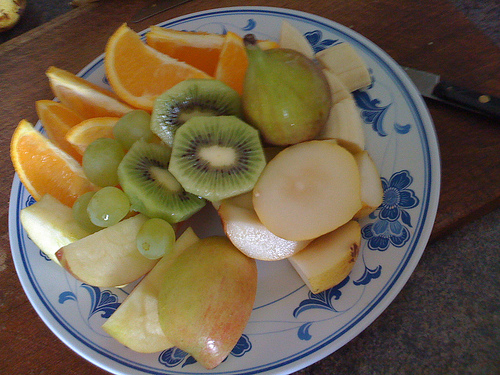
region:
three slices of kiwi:
[117, 80, 263, 220]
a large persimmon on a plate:
[240, 31, 330, 145]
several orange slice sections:
[0, 23, 251, 201]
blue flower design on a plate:
[360, 170, 417, 252]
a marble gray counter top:
[295, 206, 499, 373]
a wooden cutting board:
[3, 0, 498, 373]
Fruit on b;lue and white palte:
[10, 20, 447, 372]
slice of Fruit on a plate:
[146, 84, 232, 138]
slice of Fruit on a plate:
[121, 144, 199, 226]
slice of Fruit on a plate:
[8, 114, 94, 206]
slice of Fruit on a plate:
[32, 91, 76, 141]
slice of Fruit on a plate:
[44, 63, 109, 119]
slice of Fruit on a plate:
[99, 24, 184, 113]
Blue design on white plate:
[232, 14, 263, 31]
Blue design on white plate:
[303, 26, 329, 51]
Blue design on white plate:
[350, 80, 405, 142]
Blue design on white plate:
[388, 116, 420, 145]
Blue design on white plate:
[369, 174, 418, 218]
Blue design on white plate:
[360, 214, 411, 249]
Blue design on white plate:
[351, 262, 386, 288]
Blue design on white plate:
[290, 287, 365, 317]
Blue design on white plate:
[289, 317, 322, 348]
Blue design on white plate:
[55, 282, 77, 307]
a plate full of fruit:
[7, 3, 448, 371]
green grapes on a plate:
[72, 107, 178, 254]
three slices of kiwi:
[128, 74, 256, 216]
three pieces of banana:
[315, 36, 372, 143]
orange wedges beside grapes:
[14, 24, 264, 202]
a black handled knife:
[397, 59, 497, 121]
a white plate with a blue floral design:
[16, 13, 436, 372]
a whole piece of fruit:
[234, 32, 334, 144]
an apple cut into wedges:
[21, 189, 248, 365]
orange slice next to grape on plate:
[10, 119, 97, 211]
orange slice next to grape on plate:
[31, 99, 88, 161]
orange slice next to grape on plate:
[65, 113, 119, 149]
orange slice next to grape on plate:
[46, 65, 151, 124]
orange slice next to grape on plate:
[103, 23, 216, 108]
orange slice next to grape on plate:
[148, 24, 280, 80]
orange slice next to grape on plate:
[215, 32, 247, 90]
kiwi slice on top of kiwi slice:
[167, 119, 267, 196]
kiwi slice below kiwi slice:
[151, 76, 242, 146]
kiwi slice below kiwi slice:
[116, 139, 203, 226]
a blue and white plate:
[9, 8, 491, 366]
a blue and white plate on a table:
[8, 9, 468, 374]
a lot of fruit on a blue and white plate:
[14, 15, 448, 366]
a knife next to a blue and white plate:
[10, 10, 493, 371]